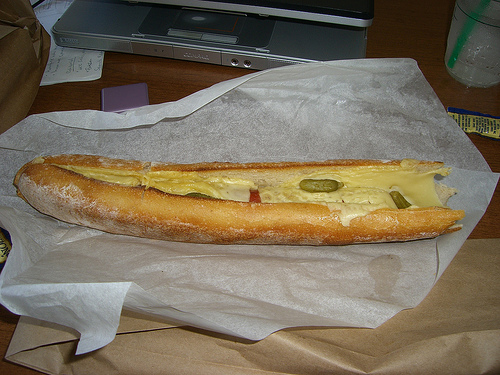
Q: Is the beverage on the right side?
A: Yes, the beverage is on the right of the image.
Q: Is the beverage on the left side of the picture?
A: No, the beverage is on the right of the image.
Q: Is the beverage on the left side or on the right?
A: The beverage is on the right of the image.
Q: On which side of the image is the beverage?
A: The beverage is on the right of the image.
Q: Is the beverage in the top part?
A: Yes, the beverage is in the top of the image.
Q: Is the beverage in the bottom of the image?
A: No, the beverage is in the top of the image.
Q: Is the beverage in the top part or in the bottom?
A: The beverage is in the top of the image.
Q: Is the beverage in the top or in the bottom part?
A: The beverage is in the top of the image.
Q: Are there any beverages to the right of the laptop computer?
A: Yes, there is a beverage to the right of the laptop computer.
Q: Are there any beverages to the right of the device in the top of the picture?
A: Yes, there is a beverage to the right of the laptop computer.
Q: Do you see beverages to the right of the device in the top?
A: Yes, there is a beverage to the right of the laptop computer.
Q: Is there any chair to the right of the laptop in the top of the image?
A: No, there is a beverage to the right of the laptop computer.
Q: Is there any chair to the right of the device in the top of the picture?
A: No, there is a beverage to the right of the laptop computer.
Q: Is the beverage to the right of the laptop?
A: Yes, the beverage is to the right of the laptop.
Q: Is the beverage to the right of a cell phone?
A: No, the beverage is to the right of the laptop.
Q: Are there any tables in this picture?
A: Yes, there is a table.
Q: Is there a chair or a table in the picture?
A: Yes, there is a table.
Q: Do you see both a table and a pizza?
A: No, there is a table but no pizzas.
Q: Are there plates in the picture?
A: No, there are no plates.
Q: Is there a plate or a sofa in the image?
A: No, there are no plates or sofas.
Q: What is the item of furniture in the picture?
A: The piece of furniture is a table.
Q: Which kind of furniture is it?
A: The piece of furniture is a table.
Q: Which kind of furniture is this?
A: This is a table.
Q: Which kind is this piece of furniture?
A: This is a table.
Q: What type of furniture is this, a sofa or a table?
A: This is a table.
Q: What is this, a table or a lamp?
A: This is a table.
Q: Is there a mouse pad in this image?
A: No, there are no mouse pads.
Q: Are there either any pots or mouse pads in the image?
A: No, there are no mouse pads or pots.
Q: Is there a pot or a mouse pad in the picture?
A: No, there are no mouse pads or pots.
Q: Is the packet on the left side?
A: No, the packet is on the right of the image.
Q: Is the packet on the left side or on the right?
A: The packet is on the right of the image.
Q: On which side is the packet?
A: The packet is on the right of the image.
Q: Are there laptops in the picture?
A: Yes, there is a laptop.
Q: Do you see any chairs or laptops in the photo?
A: Yes, there is a laptop.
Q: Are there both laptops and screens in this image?
A: No, there is a laptop but no screens.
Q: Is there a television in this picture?
A: No, there are no televisions.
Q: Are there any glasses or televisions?
A: No, there are no televisions or glasses.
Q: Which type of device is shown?
A: The device is a laptop.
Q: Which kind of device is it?
A: The device is a laptop.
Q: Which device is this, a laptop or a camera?
A: This is a laptop.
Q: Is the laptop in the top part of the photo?
A: Yes, the laptop is in the top of the image.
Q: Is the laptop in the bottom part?
A: No, the laptop is in the top of the image.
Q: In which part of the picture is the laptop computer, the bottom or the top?
A: The laptop computer is in the top of the image.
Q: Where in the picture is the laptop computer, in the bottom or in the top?
A: The laptop computer is in the top of the image.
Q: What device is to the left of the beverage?
A: The device is a laptop.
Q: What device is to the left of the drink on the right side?
A: The device is a laptop.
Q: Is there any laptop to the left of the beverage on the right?
A: Yes, there is a laptop to the left of the beverage.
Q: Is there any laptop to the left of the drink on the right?
A: Yes, there is a laptop to the left of the beverage.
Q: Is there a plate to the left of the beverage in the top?
A: No, there is a laptop to the left of the beverage.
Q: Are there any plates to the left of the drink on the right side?
A: No, there is a laptop to the left of the beverage.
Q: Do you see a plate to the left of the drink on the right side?
A: No, there is a laptop to the left of the beverage.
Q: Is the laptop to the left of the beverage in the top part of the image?
A: Yes, the laptop is to the left of the beverage.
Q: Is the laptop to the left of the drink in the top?
A: Yes, the laptop is to the left of the beverage.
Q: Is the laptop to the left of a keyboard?
A: No, the laptop is to the left of the beverage.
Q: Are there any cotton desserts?
A: No, there are no cotton desserts.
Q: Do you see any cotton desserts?
A: No, there are no cotton desserts.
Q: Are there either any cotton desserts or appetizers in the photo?
A: No, there are no cotton desserts or appetizers.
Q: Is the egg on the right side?
A: Yes, the egg is on the right of the image.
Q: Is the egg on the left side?
A: No, the egg is on the right of the image.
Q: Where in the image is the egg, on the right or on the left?
A: The egg is on the right of the image.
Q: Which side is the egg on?
A: The egg is on the right of the image.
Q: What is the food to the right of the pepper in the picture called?
A: The food is an egg.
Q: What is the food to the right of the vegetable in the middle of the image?
A: The food is an egg.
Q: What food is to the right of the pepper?
A: The food is an egg.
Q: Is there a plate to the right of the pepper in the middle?
A: No, there is an egg to the right of the pepper.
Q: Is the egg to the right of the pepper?
A: Yes, the egg is to the right of the pepper.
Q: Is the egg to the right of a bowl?
A: No, the egg is to the right of the pepper.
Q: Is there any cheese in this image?
A: Yes, there is cheese.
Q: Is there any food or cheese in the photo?
A: Yes, there is cheese.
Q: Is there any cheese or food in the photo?
A: Yes, there is cheese.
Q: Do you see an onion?
A: No, there are no onions.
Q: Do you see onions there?
A: No, there are no onions.